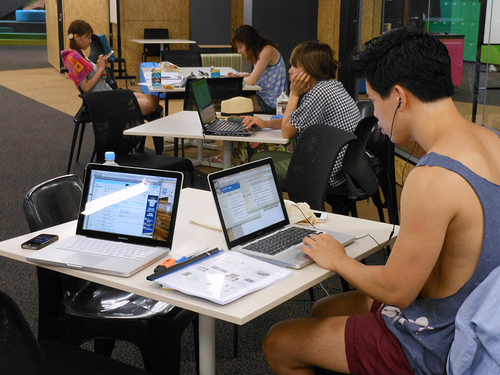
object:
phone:
[21, 232, 59, 251]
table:
[1, 186, 401, 374]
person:
[241, 40, 363, 188]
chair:
[324, 116, 385, 222]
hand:
[302, 233, 347, 269]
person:
[261, 26, 499, 374]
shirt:
[290, 78, 363, 187]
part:
[21, 171, 84, 234]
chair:
[22, 172, 200, 374]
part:
[214, 244, 392, 374]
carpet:
[0, 71, 394, 374]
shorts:
[342, 292, 413, 375]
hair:
[343, 26, 456, 103]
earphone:
[398, 98, 403, 105]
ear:
[393, 85, 408, 113]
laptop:
[207, 155, 356, 269]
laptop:
[26, 162, 185, 280]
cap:
[105, 151, 116, 160]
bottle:
[102, 151, 120, 166]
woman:
[60, 18, 160, 171]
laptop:
[189, 77, 256, 138]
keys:
[244, 226, 324, 255]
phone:
[103, 49, 115, 61]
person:
[226, 23, 289, 113]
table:
[140, 66, 263, 95]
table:
[124, 109, 298, 144]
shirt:
[379, 124, 499, 373]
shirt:
[257, 48, 287, 108]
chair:
[74, 88, 197, 187]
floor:
[1, 40, 499, 374]